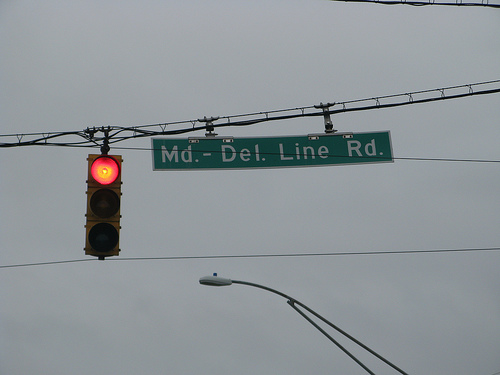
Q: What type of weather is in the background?
A: It is overcast.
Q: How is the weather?
A: It is overcast.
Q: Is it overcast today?
A: Yes, it is overcast.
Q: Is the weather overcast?
A: Yes, it is overcast.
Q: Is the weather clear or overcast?
A: It is overcast.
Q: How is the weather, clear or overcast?
A: It is overcast.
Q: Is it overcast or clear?
A: It is overcast.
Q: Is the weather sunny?
A: No, it is overcast.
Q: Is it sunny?
A: No, it is overcast.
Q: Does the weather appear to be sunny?
A: No, it is overcast.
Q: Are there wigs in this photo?
A: No, there are no wigs.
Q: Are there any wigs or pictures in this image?
A: No, there are no wigs or pictures.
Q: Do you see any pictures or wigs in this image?
A: No, there are no wigs or pictures.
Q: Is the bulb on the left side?
A: Yes, the bulb is on the left of the image.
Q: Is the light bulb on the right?
A: No, the light bulb is on the left of the image.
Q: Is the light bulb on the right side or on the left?
A: The light bulb is on the left of the image.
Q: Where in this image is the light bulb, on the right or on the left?
A: The light bulb is on the left of the image.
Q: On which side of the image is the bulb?
A: The bulb is on the left of the image.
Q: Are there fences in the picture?
A: No, there are no fences.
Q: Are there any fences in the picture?
A: No, there are no fences.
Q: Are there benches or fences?
A: No, there are no fences or benches.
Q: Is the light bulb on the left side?
A: Yes, the light bulb is on the left of the image.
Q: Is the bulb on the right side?
A: No, the bulb is on the left of the image.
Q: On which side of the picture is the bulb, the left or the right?
A: The bulb is on the left of the image.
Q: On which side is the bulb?
A: The bulb is on the left of the image.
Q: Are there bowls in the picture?
A: No, there are no bowls.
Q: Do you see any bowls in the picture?
A: No, there are no bowls.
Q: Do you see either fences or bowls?
A: No, there are no bowls or fences.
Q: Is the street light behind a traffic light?
A: Yes, the street light is behind a traffic light.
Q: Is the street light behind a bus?
A: No, the street light is behind a traffic light.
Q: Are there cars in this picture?
A: No, there are no cars.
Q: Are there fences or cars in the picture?
A: No, there are no cars or fences.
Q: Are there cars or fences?
A: No, there are no cars or fences.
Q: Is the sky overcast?
A: Yes, the sky is overcast.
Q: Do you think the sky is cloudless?
A: No, the sky is overcast.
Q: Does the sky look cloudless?
A: No, the sky is overcast.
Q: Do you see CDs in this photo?
A: No, there are no cds.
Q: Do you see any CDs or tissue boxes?
A: No, there are no CDs or tissue boxes.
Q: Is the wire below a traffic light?
A: Yes, the wire is below a traffic light.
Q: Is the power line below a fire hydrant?
A: No, the power line is below a traffic light.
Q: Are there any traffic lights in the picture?
A: Yes, there is a traffic light.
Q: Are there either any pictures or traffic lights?
A: Yes, there is a traffic light.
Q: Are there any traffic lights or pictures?
A: Yes, there is a traffic light.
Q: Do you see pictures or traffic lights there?
A: Yes, there is a traffic light.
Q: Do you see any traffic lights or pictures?
A: Yes, there is a traffic light.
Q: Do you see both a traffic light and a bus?
A: No, there is a traffic light but no buses.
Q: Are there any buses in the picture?
A: No, there are no buses.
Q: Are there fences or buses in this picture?
A: No, there are no buses or fences.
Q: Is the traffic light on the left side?
A: Yes, the traffic light is on the left of the image.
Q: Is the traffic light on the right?
A: No, the traffic light is on the left of the image.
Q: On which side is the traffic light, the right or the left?
A: The traffic light is on the left of the image.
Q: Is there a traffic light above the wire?
A: Yes, there is a traffic light above the wire.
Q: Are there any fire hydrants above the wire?
A: No, there is a traffic light above the wire.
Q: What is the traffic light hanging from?
A: The traffic light is hanging from the wire.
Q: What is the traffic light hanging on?
A: The traffic light is hanging on the wire.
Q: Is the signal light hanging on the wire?
A: Yes, the signal light is hanging on the wire.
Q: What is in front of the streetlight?
A: The signal light is in front of the streetlight.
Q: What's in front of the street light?
A: The signal light is in front of the streetlight.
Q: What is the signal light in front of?
A: The signal light is in front of the street light.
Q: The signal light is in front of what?
A: The signal light is in front of the street light.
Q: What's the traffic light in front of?
A: The signal light is in front of the street light.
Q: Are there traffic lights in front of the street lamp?
A: Yes, there is a traffic light in front of the street lamp.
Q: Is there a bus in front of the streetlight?
A: No, there is a traffic light in front of the streetlight.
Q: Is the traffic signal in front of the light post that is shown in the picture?
A: Yes, the traffic signal is in front of the light post.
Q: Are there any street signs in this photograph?
A: Yes, there is a street sign.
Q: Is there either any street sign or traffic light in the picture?
A: Yes, there is a street sign.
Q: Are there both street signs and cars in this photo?
A: No, there is a street sign but no cars.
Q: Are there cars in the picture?
A: No, there are no cars.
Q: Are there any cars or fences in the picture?
A: No, there are no cars or fences.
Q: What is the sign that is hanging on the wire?
A: The sign is a street sign.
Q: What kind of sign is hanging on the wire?
A: The sign is a street sign.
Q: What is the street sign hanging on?
A: The street sign is hanging on the wire.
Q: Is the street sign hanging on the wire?
A: Yes, the street sign is hanging on the wire.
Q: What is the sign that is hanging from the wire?
A: The sign is a street sign.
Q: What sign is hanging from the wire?
A: The sign is a street sign.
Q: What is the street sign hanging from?
A: The street sign is hanging from the wire.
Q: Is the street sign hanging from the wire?
A: Yes, the street sign is hanging from the wire.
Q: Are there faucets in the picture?
A: No, there are no faucets.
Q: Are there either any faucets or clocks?
A: No, there are no faucets or clocks.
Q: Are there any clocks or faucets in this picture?
A: No, there are no faucets or clocks.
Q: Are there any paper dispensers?
A: No, there are no paper dispensers.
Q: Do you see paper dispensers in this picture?
A: No, there are no paper dispensers.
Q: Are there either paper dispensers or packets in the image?
A: No, there are no paper dispensers or packets.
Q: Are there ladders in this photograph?
A: No, there are no ladders.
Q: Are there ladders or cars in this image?
A: No, there are no ladders or cars.